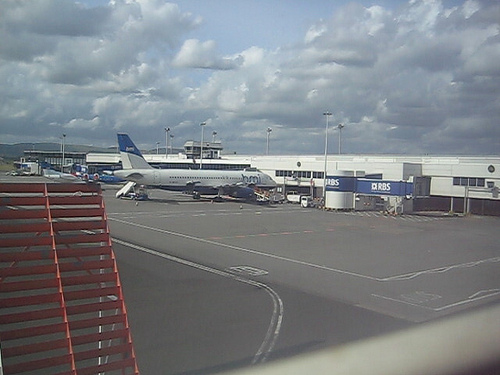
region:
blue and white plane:
[105, 134, 280, 192]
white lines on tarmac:
[175, 212, 327, 351]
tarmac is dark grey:
[148, 223, 415, 350]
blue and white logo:
[326, 169, 415, 212]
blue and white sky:
[195, 1, 389, 136]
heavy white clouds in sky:
[150, 18, 359, 121]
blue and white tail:
[119, 139, 151, 174]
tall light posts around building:
[20, 130, 346, 202]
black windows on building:
[245, 150, 340, 185]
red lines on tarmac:
[220, 202, 370, 254]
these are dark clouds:
[1, 2, 498, 154]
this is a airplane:
[92, 131, 277, 198]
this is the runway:
[2, 174, 378, 372]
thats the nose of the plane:
[263, 170, 280, 190]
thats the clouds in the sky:
[2, 3, 498, 151]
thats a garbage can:
[297, 193, 312, 209]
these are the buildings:
[7, 149, 497, 212]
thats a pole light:
[317, 110, 334, 210]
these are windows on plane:
[167, 173, 244, 181]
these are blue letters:
[320, 175, 412, 197]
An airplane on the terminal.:
[83, 127, 280, 201]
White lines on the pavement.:
[153, 208, 372, 341]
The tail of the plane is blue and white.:
[107, 118, 152, 168]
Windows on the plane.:
[169, 168, 238, 180]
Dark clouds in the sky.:
[65, 35, 415, 145]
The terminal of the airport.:
[256, 138, 498, 210]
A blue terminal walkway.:
[352, 171, 427, 196]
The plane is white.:
[123, 155, 211, 200]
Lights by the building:
[315, 103, 360, 209]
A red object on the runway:
[33, 181, 128, 366]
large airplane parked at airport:
[105, 131, 286, 197]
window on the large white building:
[310, 168, 330, 181]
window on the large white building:
[448, 174, 488, 187]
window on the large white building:
[291, 166, 313, 179]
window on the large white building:
[272, 168, 294, 178]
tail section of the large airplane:
[105, 131, 162, 186]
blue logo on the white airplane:
[240, 170, 265, 186]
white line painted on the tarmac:
[110, 230, 291, 374]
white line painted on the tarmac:
[107, 211, 394, 287]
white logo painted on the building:
[367, 180, 395, 192]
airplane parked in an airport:
[96, 130, 301, 222]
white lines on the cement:
[167, 219, 457, 344]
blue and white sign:
[357, 170, 415, 202]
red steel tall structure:
[10, 172, 160, 372]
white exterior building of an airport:
[414, 143, 489, 246]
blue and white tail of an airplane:
[107, 127, 162, 185]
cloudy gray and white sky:
[237, 73, 454, 131]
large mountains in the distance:
[12, 130, 77, 175]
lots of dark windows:
[166, 166, 251, 187]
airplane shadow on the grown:
[145, 190, 283, 221]